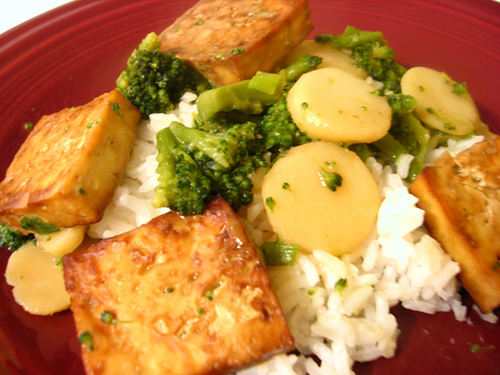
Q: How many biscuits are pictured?
A: Four.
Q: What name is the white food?
A: Rice.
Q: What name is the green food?
A: Broccoli.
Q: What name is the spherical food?
A: Potato.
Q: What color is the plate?
A: Red.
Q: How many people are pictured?
A: None.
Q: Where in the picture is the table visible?
A: Top left.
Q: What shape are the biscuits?
A: Square.